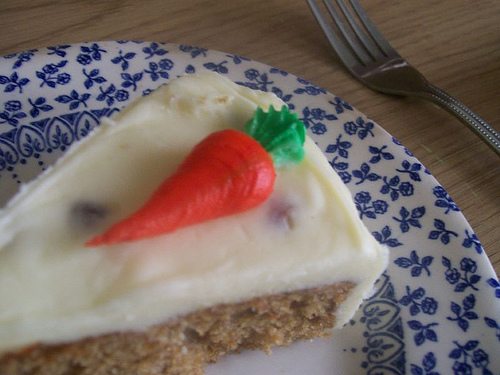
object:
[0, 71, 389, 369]
cake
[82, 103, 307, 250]
carrot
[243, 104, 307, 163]
green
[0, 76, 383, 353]
top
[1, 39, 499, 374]
dish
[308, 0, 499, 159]
fork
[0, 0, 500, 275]
table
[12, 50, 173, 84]
pattern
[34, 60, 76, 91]
flower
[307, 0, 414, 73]
prongs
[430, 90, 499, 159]
handle